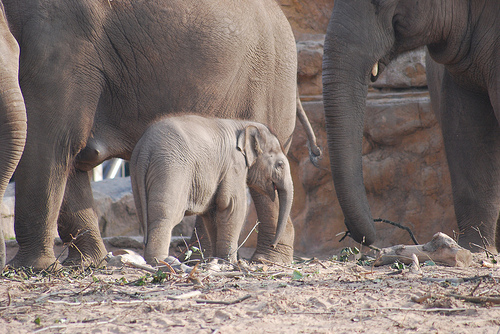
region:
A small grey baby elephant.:
[129, 115, 293, 262]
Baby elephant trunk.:
[270, 166, 291, 246]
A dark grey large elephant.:
[320, 0, 495, 251]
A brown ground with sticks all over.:
[5, 246, 495, 328]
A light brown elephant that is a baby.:
[125, 115, 292, 270]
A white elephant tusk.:
[371, 58, 378, 75]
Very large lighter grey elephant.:
[0, 0, 317, 270]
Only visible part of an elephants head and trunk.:
[0, 5, 25, 200]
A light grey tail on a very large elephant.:
[295, 91, 320, 161]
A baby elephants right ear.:
[235, 125, 261, 166]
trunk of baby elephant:
[273, 183, 296, 255]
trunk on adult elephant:
[337, 28, 369, 247]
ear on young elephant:
[237, 126, 263, 168]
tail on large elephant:
[294, 93, 316, 156]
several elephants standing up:
[0, 3, 499, 296]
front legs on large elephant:
[26, 140, 96, 267]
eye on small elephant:
[275, 158, 288, 168]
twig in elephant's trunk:
[331, 220, 417, 242]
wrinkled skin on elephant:
[122, 5, 284, 116]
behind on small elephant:
[145, 126, 185, 168]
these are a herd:
[17, 43, 384, 315]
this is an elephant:
[64, 33, 318, 241]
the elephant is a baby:
[132, 105, 326, 276]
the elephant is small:
[128, 102, 249, 189]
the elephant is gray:
[165, 113, 316, 250]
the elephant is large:
[92, 33, 240, 128]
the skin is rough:
[67, 38, 252, 159]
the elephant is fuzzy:
[120, 103, 278, 198]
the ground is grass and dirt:
[57, 243, 229, 325]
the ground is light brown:
[151, 275, 302, 326]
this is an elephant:
[95, 102, 329, 277]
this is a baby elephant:
[122, 93, 316, 291]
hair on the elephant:
[125, 88, 280, 153]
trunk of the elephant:
[309, 11, 413, 262]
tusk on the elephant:
[356, 35, 388, 85]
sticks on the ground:
[57, 199, 477, 297]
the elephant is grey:
[100, 85, 313, 262]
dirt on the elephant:
[19, 8, 336, 250]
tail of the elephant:
[128, 145, 160, 250]